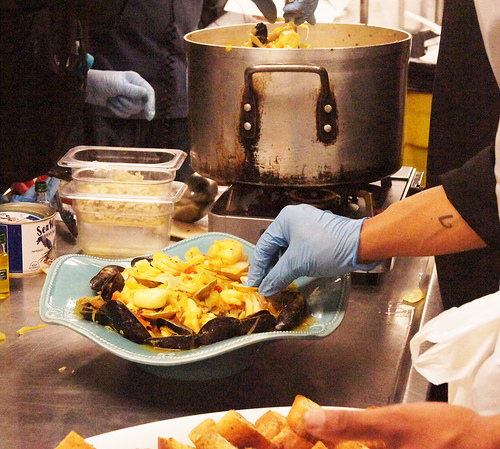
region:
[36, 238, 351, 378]
a dish served in a blue bowl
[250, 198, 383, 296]
a worker wears blue gloves while preparing food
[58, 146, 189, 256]
clear plastic double stacked containers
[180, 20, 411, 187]
big metal pot sits on the stove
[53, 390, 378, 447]
a white plate containing bread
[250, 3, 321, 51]
a blue gloved hand stirs the pot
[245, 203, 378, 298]
the worker is arranging the food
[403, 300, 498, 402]
white apron tied around the waist of the worker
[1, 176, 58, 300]
multiple ingredients on the counter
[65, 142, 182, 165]
a dish containing food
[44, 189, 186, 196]
a dish containing food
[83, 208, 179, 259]
a dish containing food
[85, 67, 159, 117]
a hand with gloves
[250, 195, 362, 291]
a hand with gloves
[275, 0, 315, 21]
a hand with gloves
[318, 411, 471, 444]
this is the thumb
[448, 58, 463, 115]
this is a black apron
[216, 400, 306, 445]
these are slices of bread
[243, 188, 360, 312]
The gloves are blue.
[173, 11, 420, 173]
The pot is silver.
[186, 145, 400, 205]
The pot is burnt.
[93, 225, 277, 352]
The chips are in the bowl.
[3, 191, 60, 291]
The can is open.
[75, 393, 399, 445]
The bread is on the plate.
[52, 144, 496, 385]
The man is grabbing some food from the bowl.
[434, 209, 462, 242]
tattoo on man's arm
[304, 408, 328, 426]
fingernail on man's thumb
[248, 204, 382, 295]
blue glove on man's hand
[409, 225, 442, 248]
vein in the man's arm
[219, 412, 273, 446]
potato wedges on plate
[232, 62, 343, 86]
handle on the pot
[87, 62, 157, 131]
latex glove on hand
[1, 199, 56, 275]
blue and white can on table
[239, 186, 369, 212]
burner on stove top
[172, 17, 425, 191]
silver pot on burner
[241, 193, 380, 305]
blue pastic safety gloves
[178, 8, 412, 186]
large silver cooking pot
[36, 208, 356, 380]
decorative warped blue bowl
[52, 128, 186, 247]
two clear plastic containers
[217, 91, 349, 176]
rust on the cooking pot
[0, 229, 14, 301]
small bottle of alcohol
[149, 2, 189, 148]
black curly wire hanging from person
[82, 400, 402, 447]
white plate with food on it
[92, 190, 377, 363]
person arranging food on plate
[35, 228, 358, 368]
a blue bowl of food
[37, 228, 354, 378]
a bowl of food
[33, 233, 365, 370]
a large wavy platter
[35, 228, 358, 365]
a wavy blue bowl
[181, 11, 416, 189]
a large metal pot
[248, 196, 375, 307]
a blue latex glove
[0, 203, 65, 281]
small white and blue can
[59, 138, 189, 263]
two empty plastic containers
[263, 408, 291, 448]
bread on the plate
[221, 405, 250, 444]
bread on the plate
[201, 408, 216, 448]
bread on the plate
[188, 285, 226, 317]
chips in a bowl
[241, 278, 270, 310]
chips in a bowl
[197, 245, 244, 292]
chips in a bowl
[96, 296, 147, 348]
a cooked mussel on a plate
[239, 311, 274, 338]
a cooked mussel on a plate